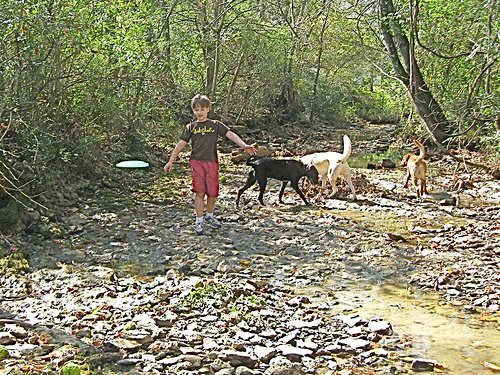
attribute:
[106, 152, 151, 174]
frisbee — light blue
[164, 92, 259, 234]
boy — young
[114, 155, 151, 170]
frisbee — white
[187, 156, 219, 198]
pants — red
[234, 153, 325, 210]
dog — three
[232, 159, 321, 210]
dog — black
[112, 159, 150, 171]
frisbee — green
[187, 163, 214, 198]
shorts — red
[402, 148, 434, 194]
dog — brown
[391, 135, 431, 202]
dog — brown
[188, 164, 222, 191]
shorts — red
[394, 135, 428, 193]
dog — brown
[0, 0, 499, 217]
trees — green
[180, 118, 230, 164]
t-shirt — black